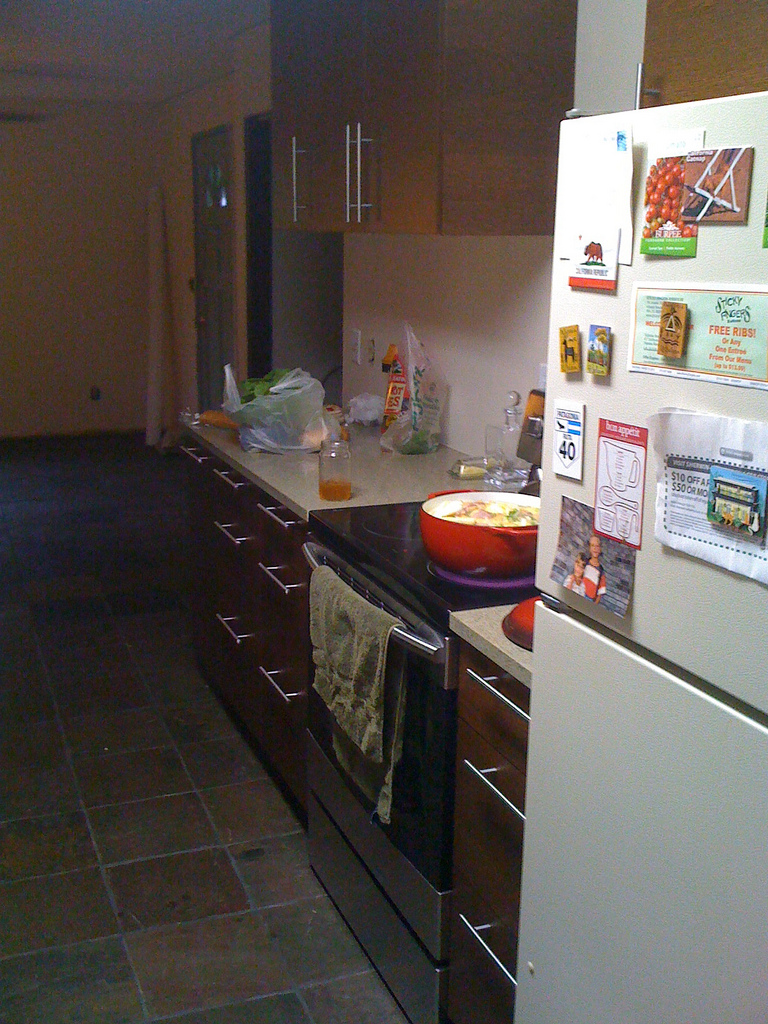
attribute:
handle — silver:
[456, 756, 523, 823]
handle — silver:
[456, 911, 517, 985]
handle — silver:
[257, 555, 303, 595]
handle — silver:
[213, 608, 249, 649]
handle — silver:
[458, 756, 526, 817]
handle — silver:
[460, 671, 529, 714]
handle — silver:
[259, 663, 299, 706]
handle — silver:
[215, 604, 252, 651]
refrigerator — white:
[510, 69, 765, 1018]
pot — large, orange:
[409, 490, 557, 573]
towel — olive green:
[299, 553, 417, 842]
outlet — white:
[348, 321, 371, 376]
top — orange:
[496, 590, 551, 650]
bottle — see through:
[482, 388, 533, 495]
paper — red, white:
[588, 413, 655, 555]